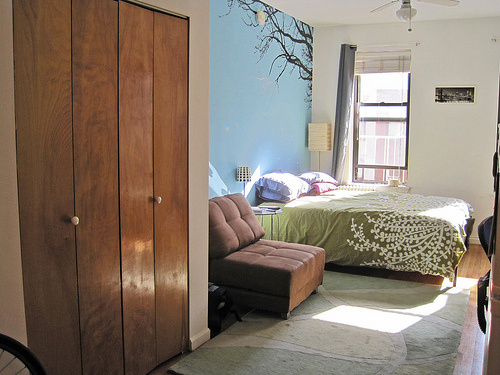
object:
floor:
[455, 244, 489, 278]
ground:
[148, 225, 491, 375]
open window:
[353, 72, 408, 185]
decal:
[205, 0, 311, 202]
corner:
[296, 23, 329, 122]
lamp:
[236, 167, 251, 194]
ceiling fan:
[365, 0, 460, 13]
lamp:
[395, 1, 418, 22]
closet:
[0, 0, 210, 375]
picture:
[435, 87, 475, 104]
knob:
[155, 196, 162, 204]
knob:
[71, 217, 81, 224]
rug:
[167, 274, 470, 374]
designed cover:
[344, 194, 470, 277]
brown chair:
[209, 192, 324, 318]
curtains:
[332, 45, 354, 180]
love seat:
[209, 192, 324, 319]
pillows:
[256, 171, 338, 202]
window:
[351, 52, 407, 185]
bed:
[252, 190, 468, 285]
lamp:
[308, 123, 331, 172]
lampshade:
[237, 167, 252, 183]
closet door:
[14, 0, 190, 375]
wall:
[203, 0, 500, 243]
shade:
[304, 123, 331, 151]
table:
[252, 207, 282, 216]